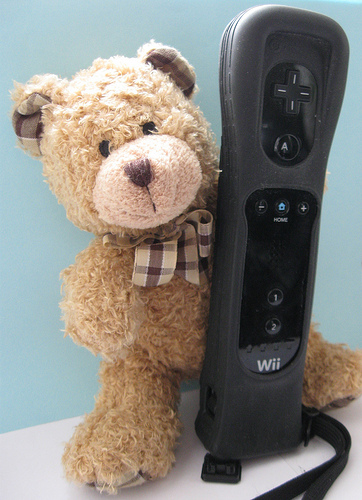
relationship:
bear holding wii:
[9, 39, 361, 498] [193, 4, 351, 462]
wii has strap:
[193, 4, 351, 462] [250, 401, 351, 499]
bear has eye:
[9, 39, 361, 498] [99, 138, 112, 159]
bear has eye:
[9, 39, 361, 498] [141, 121, 160, 135]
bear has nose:
[9, 39, 361, 498] [125, 158, 154, 187]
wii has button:
[193, 4, 351, 462] [265, 318, 283, 334]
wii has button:
[193, 4, 351, 462] [267, 288, 283, 306]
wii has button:
[193, 4, 351, 462] [254, 199, 269, 215]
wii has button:
[193, 4, 351, 462] [273, 198, 290, 214]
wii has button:
[193, 4, 351, 462] [298, 202, 309, 214]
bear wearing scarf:
[9, 39, 361, 498] [102, 208, 214, 286]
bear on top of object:
[9, 39, 361, 498] [2, 388, 362, 500]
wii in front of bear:
[193, 4, 351, 462] [9, 39, 361, 498]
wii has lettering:
[193, 4, 351, 462] [257, 356, 283, 373]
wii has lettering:
[193, 4, 351, 462] [273, 215, 289, 225]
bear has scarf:
[9, 39, 361, 498] [102, 208, 214, 286]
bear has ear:
[9, 39, 361, 498] [138, 38, 198, 101]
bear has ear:
[9, 39, 361, 498] [8, 71, 66, 161]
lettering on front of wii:
[257, 356, 283, 373] [193, 4, 351, 462]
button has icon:
[273, 198, 290, 214] [279, 203, 285, 212]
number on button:
[273, 294, 278, 304] [267, 288, 283, 306]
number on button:
[271, 323, 277, 333] [265, 318, 283, 334]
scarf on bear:
[102, 208, 214, 286] [9, 39, 361, 498]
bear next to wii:
[9, 39, 361, 498] [193, 4, 351, 462]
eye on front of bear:
[99, 138, 112, 159] [9, 39, 361, 498]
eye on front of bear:
[141, 121, 160, 135] [9, 39, 361, 498]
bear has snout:
[9, 39, 361, 498] [93, 134, 201, 228]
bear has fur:
[9, 39, 361, 498] [8, 37, 360, 494]